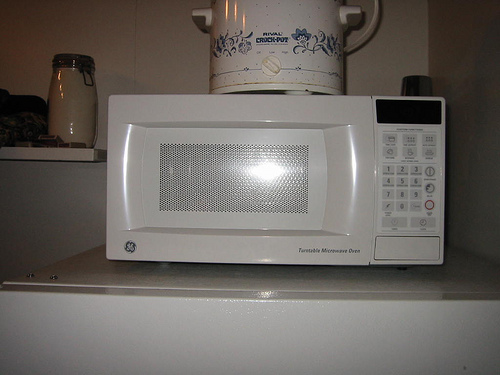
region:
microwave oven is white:
[99, 93, 456, 271]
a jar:
[40, 40, 101, 160]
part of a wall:
[478, 209, 488, 215]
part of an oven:
[292, 218, 304, 233]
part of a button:
[389, 186, 397, 199]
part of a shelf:
[33, 117, 46, 142]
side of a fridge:
[296, 323, 308, 333]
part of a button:
[354, 202, 376, 224]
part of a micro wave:
[418, 244, 427, 255]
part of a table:
[437, 300, 449, 310]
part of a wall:
[472, 200, 487, 207]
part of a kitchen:
[244, 332, 271, 367]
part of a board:
[75, 191, 92, 208]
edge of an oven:
[238, 226, 267, 251]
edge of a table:
[266, 279, 292, 329]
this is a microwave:
[107, 93, 447, 267]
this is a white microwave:
[103, 89, 448, 266]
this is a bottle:
[49, 50, 96, 152]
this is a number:
[384, 165, 393, 175]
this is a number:
[398, 161, 410, 173]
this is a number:
[411, 163, 419, 177]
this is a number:
[386, 172, 396, 187]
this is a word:
[253, 31, 292, 46]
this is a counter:
[4, 136, 104, 167]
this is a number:
[398, 202, 408, 213]